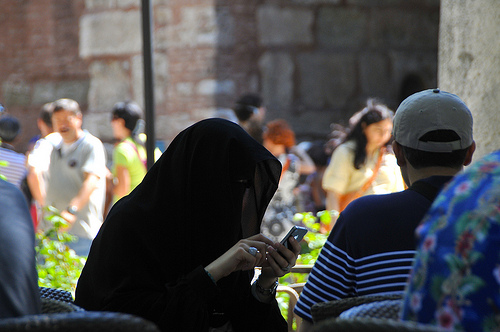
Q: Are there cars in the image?
A: No, there are no cars.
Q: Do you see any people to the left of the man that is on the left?
A: Yes, there is a person to the left of the man.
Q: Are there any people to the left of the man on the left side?
A: Yes, there is a person to the left of the man.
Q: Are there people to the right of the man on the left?
A: No, the person is to the left of the man.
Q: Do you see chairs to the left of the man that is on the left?
A: No, there is a person to the left of the man.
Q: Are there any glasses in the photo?
A: No, there are no glasses.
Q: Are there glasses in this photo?
A: No, there are no glasses.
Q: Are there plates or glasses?
A: No, there are no glasses or plates.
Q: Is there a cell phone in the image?
A: Yes, there is a cell phone.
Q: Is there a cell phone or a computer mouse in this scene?
A: Yes, there is a cell phone.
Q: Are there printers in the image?
A: No, there are no printers.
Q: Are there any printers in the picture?
A: No, there are no printers.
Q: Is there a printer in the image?
A: No, there are no printers.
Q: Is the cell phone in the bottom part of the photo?
A: Yes, the cell phone is in the bottom of the image.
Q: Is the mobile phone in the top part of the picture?
A: No, the mobile phone is in the bottom of the image.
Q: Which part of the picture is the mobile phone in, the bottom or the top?
A: The mobile phone is in the bottom of the image.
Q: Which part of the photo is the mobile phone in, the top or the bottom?
A: The mobile phone is in the bottom of the image.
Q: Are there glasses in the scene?
A: No, there are no glasses.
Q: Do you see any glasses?
A: No, there are no glasses.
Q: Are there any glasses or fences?
A: No, there are no glasses or fences.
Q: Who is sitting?
A: The man is sitting.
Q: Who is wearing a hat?
A: The man is wearing a hat.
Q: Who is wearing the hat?
A: The man is wearing a hat.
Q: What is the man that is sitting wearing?
A: The man is wearing a hat.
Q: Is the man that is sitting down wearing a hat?
A: Yes, the man is wearing a hat.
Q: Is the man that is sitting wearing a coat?
A: No, the man is wearing a hat.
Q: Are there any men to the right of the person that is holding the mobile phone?
A: Yes, there is a man to the right of the person.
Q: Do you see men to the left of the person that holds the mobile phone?
A: No, the man is to the right of the person.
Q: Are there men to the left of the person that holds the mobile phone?
A: No, the man is to the right of the person.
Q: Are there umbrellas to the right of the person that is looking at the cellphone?
A: No, there is a man to the right of the person.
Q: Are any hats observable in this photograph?
A: Yes, there is a hat.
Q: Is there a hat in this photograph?
A: Yes, there is a hat.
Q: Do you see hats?
A: Yes, there is a hat.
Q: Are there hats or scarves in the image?
A: Yes, there is a hat.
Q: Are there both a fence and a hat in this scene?
A: No, there is a hat but no fences.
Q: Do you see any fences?
A: No, there are no fences.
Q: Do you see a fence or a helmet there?
A: No, there are no fences or helmets.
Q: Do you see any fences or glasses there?
A: No, there are no glasses or fences.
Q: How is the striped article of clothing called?
A: The clothing item is a shirt.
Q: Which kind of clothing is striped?
A: The clothing is a shirt.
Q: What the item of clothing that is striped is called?
A: The clothing item is a shirt.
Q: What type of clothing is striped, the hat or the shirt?
A: The shirt is striped.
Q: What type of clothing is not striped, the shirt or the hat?
A: The hat is not striped.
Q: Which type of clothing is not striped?
A: The clothing is a hat.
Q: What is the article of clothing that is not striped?
A: The clothing item is a hat.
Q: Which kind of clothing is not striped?
A: The clothing is a hat.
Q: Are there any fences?
A: No, there are no fences.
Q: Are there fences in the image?
A: No, there are no fences.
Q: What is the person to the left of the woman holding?
A: The person is holding the mobile phone.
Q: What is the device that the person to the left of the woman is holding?
A: The device is a cell phone.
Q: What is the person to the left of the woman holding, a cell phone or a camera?
A: The person is holding a cell phone.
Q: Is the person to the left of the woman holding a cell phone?
A: Yes, the person is holding a cell phone.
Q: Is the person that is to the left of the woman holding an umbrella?
A: No, the person is holding a cell phone.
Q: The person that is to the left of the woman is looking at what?
A: The person is looking at the cell phone.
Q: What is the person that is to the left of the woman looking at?
A: The person is looking at the cell phone.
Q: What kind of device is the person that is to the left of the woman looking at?
A: The person is looking at the mobile phone.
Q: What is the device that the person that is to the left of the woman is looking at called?
A: The device is a cell phone.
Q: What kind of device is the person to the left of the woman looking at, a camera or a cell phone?
A: The person is looking at a cell phone.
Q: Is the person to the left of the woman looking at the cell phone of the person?
A: Yes, the person is looking at the mobile phone.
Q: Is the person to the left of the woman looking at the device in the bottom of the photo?
A: Yes, the person is looking at the mobile phone.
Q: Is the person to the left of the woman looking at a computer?
A: No, the person is looking at the mobile phone.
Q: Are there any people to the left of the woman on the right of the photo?
A: Yes, there is a person to the left of the woman.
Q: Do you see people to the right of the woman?
A: No, the person is to the left of the woman.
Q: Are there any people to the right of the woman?
A: No, the person is to the left of the woman.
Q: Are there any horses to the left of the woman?
A: No, there is a person to the left of the woman.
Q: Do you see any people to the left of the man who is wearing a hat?
A: Yes, there is a person to the left of the man.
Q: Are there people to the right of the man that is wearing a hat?
A: No, the person is to the left of the man.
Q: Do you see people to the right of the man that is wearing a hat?
A: No, the person is to the left of the man.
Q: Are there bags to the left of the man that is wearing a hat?
A: No, there is a person to the left of the man.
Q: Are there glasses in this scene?
A: No, there are no glasses.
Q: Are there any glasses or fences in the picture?
A: No, there are no glasses or fences.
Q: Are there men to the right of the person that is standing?
A: Yes, there is a man to the right of the person.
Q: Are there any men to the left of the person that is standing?
A: No, the man is to the right of the person.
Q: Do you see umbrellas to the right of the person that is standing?
A: No, there is a man to the right of the person.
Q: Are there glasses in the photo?
A: No, there are no glasses.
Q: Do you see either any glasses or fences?
A: No, there are no glasses or fences.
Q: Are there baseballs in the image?
A: No, there are no baseballs.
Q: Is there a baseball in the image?
A: No, there are no baseballs.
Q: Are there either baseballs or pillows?
A: No, there are no baseballs or pillows.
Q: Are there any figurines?
A: No, there are no figurines.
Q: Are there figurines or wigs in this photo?
A: No, there are no figurines or wigs.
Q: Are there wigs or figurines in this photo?
A: No, there are no figurines or wigs.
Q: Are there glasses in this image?
A: No, there are no glasses.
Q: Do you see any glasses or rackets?
A: No, there are no glasses or rackets.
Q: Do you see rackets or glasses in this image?
A: No, there are no glasses or rackets.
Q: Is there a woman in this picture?
A: Yes, there is a woman.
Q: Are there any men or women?
A: Yes, there is a woman.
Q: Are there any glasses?
A: No, there are no glasses.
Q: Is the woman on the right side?
A: Yes, the woman is on the right of the image.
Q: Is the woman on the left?
A: No, the woman is on the right of the image.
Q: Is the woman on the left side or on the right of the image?
A: The woman is on the right of the image.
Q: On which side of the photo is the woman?
A: The woman is on the right of the image.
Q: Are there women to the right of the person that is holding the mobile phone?
A: Yes, there is a woman to the right of the person.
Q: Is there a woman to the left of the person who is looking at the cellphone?
A: No, the woman is to the right of the person.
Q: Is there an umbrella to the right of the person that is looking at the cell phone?
A: No, there is a woman to the right of the person.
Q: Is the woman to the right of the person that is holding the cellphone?
A: Yes, the woman is to the right of the person.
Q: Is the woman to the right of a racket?
A: No, the woman is to the right of the person.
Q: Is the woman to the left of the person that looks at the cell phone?
A: No, the woman is to the right of the person.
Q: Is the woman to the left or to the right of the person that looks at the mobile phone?
A: The woman is to the right of the person.